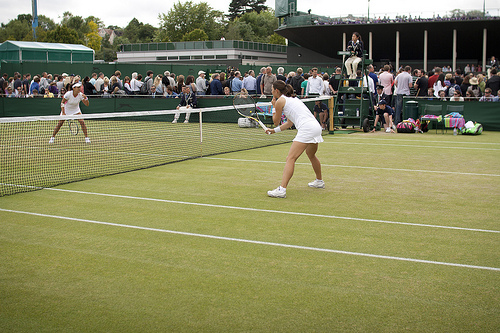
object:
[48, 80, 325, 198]
players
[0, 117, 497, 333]
tennis court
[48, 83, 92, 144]
player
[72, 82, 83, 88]
hat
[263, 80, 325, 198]
player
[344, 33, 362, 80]
judge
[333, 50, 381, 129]
ladder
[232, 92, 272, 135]
tennis racket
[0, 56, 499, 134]
people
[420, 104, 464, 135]
chairs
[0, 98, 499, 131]
wall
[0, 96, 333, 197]
net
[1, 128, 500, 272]
lines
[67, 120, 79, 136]
tennis racket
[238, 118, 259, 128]
bags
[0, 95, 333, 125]
top of net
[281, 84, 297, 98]
ponytail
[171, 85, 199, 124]
man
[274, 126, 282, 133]
wristband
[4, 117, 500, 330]
grass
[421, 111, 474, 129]
towels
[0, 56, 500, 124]
stands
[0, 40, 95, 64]
building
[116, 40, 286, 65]
building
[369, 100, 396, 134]
ball shagger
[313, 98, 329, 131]
ball shagger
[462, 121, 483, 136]
bag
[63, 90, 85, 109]
shirt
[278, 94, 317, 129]
shirt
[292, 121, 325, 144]
skirt